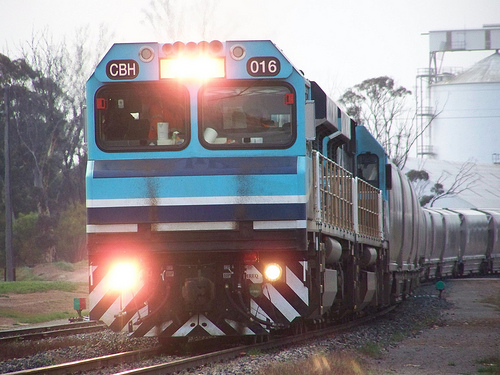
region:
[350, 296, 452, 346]
Rocks next to the tracks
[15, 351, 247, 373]
Track in front of the approaching train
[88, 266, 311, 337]
Black and white striped bottom of the train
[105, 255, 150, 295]
Brighter larger light on the bottom left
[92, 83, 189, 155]
Window in the front on the left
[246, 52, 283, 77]
The number 016 on the front of the train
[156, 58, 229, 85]
Light on the top of the front of the train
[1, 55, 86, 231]
Trees to the left of the train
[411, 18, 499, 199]
Large white structure behind the train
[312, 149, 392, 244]
Fenced in area on the train's side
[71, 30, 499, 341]
The train traveling on the tracks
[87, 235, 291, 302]
The headlights at the bottom of the train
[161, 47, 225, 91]
The headlights on the top of the train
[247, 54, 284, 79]
The number 016 on the train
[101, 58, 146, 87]
CBH printed on the front of the train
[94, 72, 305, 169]
The windows on the front of the train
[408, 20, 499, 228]
The large white structure behind the train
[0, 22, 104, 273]
The trees to the train's right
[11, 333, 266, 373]
The tracks in front of the train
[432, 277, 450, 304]
The green circle next to the train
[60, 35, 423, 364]
The train is on the tracks.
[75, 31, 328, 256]
The train is blue.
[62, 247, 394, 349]
The train's bottom is black and white.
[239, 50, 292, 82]
The number 016 is on the train.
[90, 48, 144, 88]
The letters CBH are on the train.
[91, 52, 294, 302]
Three front lights are on the train.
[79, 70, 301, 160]
The train has two front windows.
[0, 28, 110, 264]
Trees are in the background.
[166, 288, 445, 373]
Gravel is next to the tracks.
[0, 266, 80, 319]
Grass grows next to the tracks.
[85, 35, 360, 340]
two tone blue and white train engine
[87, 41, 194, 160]
CBH above right-hand windshield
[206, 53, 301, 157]
016 above left-hand windshield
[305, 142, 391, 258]
safety railing along left side of engine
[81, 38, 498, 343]
train pulling silver boxcars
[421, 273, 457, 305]
green marker beside railroad tracks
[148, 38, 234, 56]
air horns above light on engine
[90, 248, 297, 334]
two lower lights illuminated on train engine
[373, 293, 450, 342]
rocks and gravel on ground beside tracks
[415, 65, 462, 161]
ladder on side of storage bin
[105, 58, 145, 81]
The three letters on the front of the train.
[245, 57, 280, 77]
The three numbers on the front of the train.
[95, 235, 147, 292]
The left bottom headlight on the train.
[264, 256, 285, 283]
The right lower headlight on the train.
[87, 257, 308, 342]
The black and white stripes on the front of the train.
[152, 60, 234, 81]
The rectangular shaped light at the top of the train.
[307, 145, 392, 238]
The silver gate on the side of the train.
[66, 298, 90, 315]
The red and green reflector to the left of the train.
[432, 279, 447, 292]
The green reflector to the right of the train.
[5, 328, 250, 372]
The train tracks in front of the train.